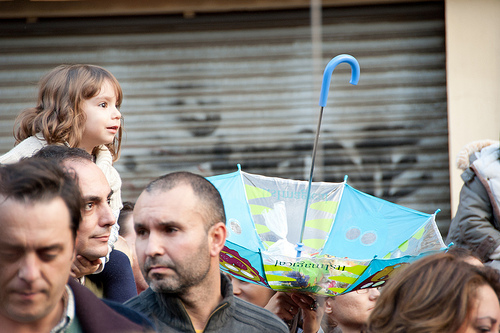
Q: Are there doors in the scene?
A: Yes, there is a door.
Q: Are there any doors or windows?
A: Yes, there is a door.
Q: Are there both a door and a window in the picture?
A: No, there is a door but no windows.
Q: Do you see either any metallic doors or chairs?
A: Yes, there is a metal door.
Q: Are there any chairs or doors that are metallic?
A: Yes, the door is metallic.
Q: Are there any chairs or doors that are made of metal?
A: Yes, the door is made of metal.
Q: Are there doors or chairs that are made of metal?
A: Yes, the door is made of metal.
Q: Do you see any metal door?
A: Yes, there is a door that is made of metal.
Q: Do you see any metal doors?
A: Yes, there is a door that is made of metal.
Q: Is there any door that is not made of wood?
A: Yes, there is a door that is made of metal.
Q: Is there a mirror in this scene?
A: No, there are no mirrors.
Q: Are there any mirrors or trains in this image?
A: No, there are no mirrors or trains.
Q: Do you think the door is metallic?
A: Yes, the door is metallic.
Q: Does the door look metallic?
A: Yes, the door is metallic.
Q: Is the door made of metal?
A: Yes, the door is made of metal.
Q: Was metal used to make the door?
A: Yes, the door is made of metal.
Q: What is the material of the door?
A: The door is made of metal.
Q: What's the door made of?
A: The door is made of metal.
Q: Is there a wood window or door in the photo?
A: No, there is a door but it is metallic.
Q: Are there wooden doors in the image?
A: No, there is a door but it is metallic.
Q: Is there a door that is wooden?
A: No, there is a door but it is metallic.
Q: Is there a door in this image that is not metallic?
A: No, there is a door but it is metallic.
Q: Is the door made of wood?
A: No, the door is made of metal.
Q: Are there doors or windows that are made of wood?
A: No, there is a door but it is made of metal.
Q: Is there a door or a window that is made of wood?
A: No, there is a door but it is made of metal.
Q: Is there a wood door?
A: No, there is a door but it is made of metal.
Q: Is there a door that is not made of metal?
A: No, there is a door but it is made of metal.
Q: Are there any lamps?
A: No, there are no lamps.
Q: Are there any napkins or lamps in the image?
A: No, there are no lamps or napkins.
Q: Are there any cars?
A: No, there are no cars.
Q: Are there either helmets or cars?
A: No, there are no cars or helmets.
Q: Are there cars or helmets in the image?
A: No, there are no cars or helmets.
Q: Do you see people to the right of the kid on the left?
A: Yes, there is a person to the right of the child.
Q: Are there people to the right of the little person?
A: Yes, there is a person to the right of the child.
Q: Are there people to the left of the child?
A: No, the person is to the right of the child.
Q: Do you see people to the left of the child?
A: No, the person is to the right of the child.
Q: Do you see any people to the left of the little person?
A: No, the person is to the right of the child.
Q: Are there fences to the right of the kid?
A: No, there is a person to the right of the kid.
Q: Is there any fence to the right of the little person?
A: No, there is a person to the right of the kid.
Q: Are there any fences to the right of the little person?
A: No, there is a person to the right of the kid.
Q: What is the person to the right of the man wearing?
A: The person is wearing a sweater.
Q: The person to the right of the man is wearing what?
A: The person is wearing a sweater.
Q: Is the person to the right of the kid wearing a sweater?
A: Yes, the person is wearing a sweater.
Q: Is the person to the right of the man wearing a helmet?
A: No, the person is wearing a sweater.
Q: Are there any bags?
A: No, there are no bags.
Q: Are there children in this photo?
A: Yes, there is a child.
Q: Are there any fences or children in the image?
A: Yes, there is a child.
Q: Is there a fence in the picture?
A: No, there are no fences.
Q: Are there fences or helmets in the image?
A: No, there are no fences or helmets.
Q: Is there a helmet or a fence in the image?
A: No, there are no fences or helmets.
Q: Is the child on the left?
A: Yes, the child is on the left of the image.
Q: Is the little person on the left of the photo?
A: Yes, the child is on the left of the image.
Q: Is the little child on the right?
A: No, the child is on the left of the image.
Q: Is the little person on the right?
A: No, the child is on the left of the image.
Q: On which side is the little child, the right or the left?
A: The child is on the left of the image.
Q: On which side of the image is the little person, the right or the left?
A: The child is on the left of the image.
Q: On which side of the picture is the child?
A: The child is on the left of the image.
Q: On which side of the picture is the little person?
A: The child is on the left of the image.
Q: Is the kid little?
A: Yes, the kid is little.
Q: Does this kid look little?
A: Yes, the kid is little.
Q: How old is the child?
A: The child is little.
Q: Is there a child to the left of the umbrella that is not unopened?
A: Yes, there is a child to the left of the umbrella.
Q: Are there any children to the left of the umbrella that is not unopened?
A: Yes, there is a child to the left of the umbrella.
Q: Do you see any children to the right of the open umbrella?
A: No, the child is to the left of the umbrella.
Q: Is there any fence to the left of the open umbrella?
A: No, there is a child to the left of the umbrella.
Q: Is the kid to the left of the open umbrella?
A: Yes, the kid is to the left of the umbrella.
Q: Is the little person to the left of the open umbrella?
A: Yes, the kid is to the left of the umbrella.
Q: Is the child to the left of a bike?
A: No, the child is to the left of the umbrella.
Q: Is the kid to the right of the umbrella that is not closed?
A: No, the kid is to the left of the umbrella.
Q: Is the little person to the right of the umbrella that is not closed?
A: No, the kid is to the left of the umbrella.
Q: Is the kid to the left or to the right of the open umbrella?
A: The kid is to the left of the umbrella.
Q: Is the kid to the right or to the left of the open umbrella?
A: The kid is to the left of the umbrella.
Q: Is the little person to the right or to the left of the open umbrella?
A: The kid is to the left of the umbrella.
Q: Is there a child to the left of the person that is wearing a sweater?
A: Yes, there is a child to the left of the person.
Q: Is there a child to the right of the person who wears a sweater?
A: No, the child is to the left of the person.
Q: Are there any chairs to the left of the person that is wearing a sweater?
A: No, there is a child to the left of the person.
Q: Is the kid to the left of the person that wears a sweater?
A: Yes, the kid is to the left of the person.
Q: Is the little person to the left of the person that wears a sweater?
A: Yes, the kid is to the left of the person.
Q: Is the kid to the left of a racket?
A: No, the kid is to the left of the person.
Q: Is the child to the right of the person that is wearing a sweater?
A: No, the child is to the left of the person.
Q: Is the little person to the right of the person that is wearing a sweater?
A: No, the child is to the left of the person.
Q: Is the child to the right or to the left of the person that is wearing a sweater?
A: The child is to the left of the person.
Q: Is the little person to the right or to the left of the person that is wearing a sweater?
A: The child is to the left of the person.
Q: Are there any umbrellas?
A: Yes, there is an umbrella.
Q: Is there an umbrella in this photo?
A: Yes, there is an umbrella.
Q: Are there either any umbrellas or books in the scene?
A: Yes, there is an umbrella.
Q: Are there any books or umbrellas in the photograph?
A: Yes, there is an umbrella.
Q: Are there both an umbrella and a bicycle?
A: No, there is an umbrella but no bicycles.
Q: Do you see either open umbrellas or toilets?
A: Yes, there is an open umbrella.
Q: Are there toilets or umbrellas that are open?
A: Yes, the umbrella is open.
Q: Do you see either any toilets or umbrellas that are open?
A: Yes, the umbrella is open.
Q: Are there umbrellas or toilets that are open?
A: Yes, the umbrella is open.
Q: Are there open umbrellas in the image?
A: Yes, there is an open umbrella.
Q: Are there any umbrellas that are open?
A: Yes, there is an umbrella that is open.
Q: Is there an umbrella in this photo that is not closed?
A: Yes, there is a open umbrella.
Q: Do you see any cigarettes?
A: No, there are no cigarettes.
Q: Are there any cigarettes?
A: No, there are no cigarettes.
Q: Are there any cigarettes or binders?
A: No, there are no cigarettes or binders.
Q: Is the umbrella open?
A: Yes, the umbrella is open.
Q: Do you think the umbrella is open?
A: Yes, the umbrella is open.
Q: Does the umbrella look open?
A: Yes, the umbrella is open.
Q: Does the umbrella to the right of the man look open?
A: Yes, the umbrella is open.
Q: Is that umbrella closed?
A: No, the umbrella is open.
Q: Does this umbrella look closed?
A: No, the umbrella is open.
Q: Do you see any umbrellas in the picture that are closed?
A: No, there is an umbrella but it is open.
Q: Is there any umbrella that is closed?
A: No, there is an umbrella but it is open.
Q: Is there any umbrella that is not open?
A: No, there is an umbrella but it is open.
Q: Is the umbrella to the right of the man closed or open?
A: The umbrella is open.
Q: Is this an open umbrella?
A: Yes, this is an open umbrella.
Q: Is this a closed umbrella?
A: No, this is an open umbrella.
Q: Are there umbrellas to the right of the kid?
A: Yes, there is an umbrella to the right of the kid.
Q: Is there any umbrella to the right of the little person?
A: Yes, there is an umbrella to the right of the kid.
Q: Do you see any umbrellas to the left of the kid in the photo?
A: No, the umbrella is to the right of the kid.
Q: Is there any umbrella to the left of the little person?
A: No, the umbrella is to the right of the kid.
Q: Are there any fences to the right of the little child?
A: No, there is an umbrella to the right of the kid.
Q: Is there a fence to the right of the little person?
A: No, there is an umbrella to the right of the kid.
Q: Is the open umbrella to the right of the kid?
A: Yes, the umbrella is to the right of the kid.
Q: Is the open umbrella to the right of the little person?
A: Yes, the umbrella is to the right of the kid.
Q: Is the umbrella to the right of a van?
A: No, the umbrella is to the right of the kid.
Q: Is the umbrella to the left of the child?
A: No, the umbrella is to the right of the child.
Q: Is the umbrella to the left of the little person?
A: No, the umbrella is to the right of the child.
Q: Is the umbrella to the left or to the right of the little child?
A: The umbrella is to the right of the kid.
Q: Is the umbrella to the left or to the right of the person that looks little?
A: The umbrella is to the right of the kid.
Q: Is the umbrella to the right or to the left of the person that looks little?
A: The umbrella is to the right of the kid.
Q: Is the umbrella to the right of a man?
A: Yes, the umbrella is to the right of a man.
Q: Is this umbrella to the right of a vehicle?
A: No, the umbrella is to the right of a man.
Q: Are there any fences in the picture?
A: No, there are no fences.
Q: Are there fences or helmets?
A: No, there are no fences or helmets.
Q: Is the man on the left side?
A: Yes, the man is on the left of the image.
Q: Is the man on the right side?
A: No, the man is on the left of the image.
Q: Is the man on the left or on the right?
A: The man is on the left of the image.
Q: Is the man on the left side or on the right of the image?
A: The man is on the left of the image.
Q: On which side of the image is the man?
A: The man is on the left of the image.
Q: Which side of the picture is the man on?
A: The man is on the left of the image.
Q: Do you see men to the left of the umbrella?
A: Yes, there is a man to the left of the umbrella.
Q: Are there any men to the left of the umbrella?
A: Yes, there is a man to the left of the umbrella.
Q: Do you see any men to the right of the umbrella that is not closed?
A: No, the man is to the left of the umbrella.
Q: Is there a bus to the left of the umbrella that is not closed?
A: No, there is a man to the left of the umbrella.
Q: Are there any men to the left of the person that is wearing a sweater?
A: Yes, there is a man to the left of the person.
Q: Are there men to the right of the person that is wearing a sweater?
A: No, the man is to the left of the person.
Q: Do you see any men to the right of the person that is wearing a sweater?
A: No, the man is to the left of the person.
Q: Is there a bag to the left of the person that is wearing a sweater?
A: No, there is a man to the left of the person.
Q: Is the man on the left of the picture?
A: Yes, the man is on the left of the image.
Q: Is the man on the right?
A: No, the man is on the left of the image.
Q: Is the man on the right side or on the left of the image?
A: The man is on the left of the image.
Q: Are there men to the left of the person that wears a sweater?
A: Yes, there is a man to the left of the person.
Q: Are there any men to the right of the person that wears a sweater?
A: No, the man is to the left of the person.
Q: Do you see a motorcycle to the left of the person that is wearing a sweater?
A: No, there is a man to the left of the person.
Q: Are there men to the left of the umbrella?
A: Yes, there is a man to the left of the umbrella.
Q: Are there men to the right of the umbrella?
A: No, the man is to the left of the umbrella.